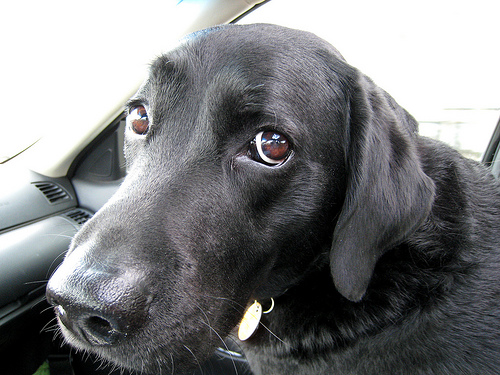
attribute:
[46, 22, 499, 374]
dog — looking, black, large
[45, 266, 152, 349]
nose — wet, large, black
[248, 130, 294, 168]
eye — brown, white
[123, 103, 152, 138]
eye — brown, white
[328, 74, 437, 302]
ear — down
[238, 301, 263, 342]
tag — silver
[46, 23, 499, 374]
fur — black, white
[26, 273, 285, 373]
whiskers — white